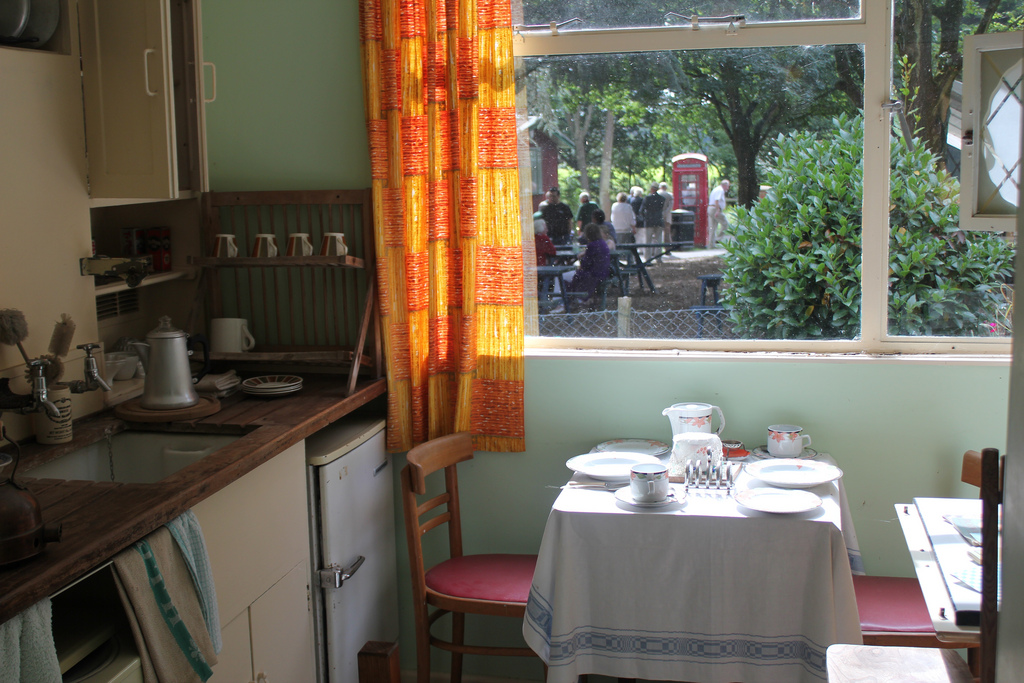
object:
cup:
[128, 316, 199, 410]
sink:
[16, 422, 262, 485]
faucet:
[76, 343, 112, 392]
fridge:
[309, 418, 402, 682]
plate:
[566, 452, 664, 482]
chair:
[402, 430, 541, 682]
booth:
[671, 153, 709, 247]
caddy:
[685, 460, 731, 496]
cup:
[630, 464, 669, 502]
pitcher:
[679, 414, 714, 428]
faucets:
[28, 359, 60, 418]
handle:
[318, 555, 365, 588]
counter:
[0, 372, 403, 682]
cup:
[211, 317, 255, 353]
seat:
[424, 553, 537, 603]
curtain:
[367, 0, 539, 455]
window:
[512, 0, 1024, 354]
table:
[528, 446, 867, 682]